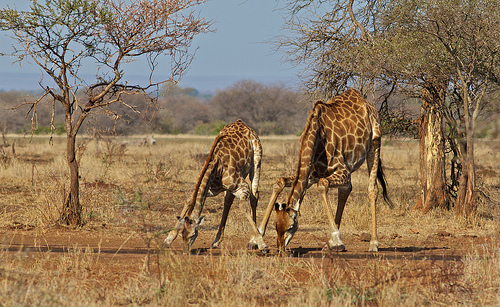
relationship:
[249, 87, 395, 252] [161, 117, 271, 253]
giraffe near giraffe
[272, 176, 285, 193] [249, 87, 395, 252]
knee of giraffe